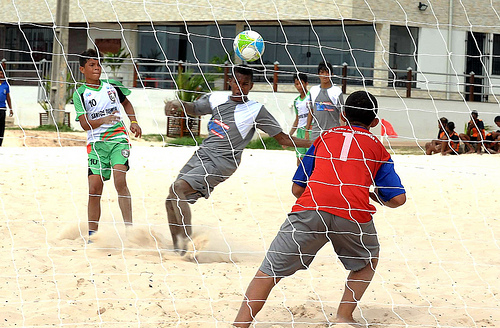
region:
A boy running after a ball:
[163, 63, 310, 262]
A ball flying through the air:
[231, 29, 263, 61]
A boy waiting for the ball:
[231, 90, 408, 324]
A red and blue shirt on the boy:
[287, 123, 404, 223]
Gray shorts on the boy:
[250, 206, 382, 279]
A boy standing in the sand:
[62, 47, 142, 248]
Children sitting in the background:
[425, 108, 498, 157]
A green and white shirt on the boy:
[69, 78, 130, 140]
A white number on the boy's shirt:
[335, 126, 356, 163]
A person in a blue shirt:
[0, 70, 14, 146]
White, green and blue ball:
[231, 26, 268, 64]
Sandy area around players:
[1, 150, 497, 326]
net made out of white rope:
[3, 5, 499, 327]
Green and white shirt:
[68, 75, 133, 137]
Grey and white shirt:
[186, 82, 281, 159]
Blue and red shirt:
[294, 126, 406, 220]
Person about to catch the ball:
[157, 70, 302, 250]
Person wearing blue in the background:
[0, 69, 15, 149]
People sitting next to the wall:
[422, 108, 497, 154]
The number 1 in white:
[328, 123, 353, 167]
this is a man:
[228, 84, 414, 326]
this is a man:
[156, 58, 329, 281]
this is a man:
[29, 40, 173, 244]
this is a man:
[281, 71, 311, 179]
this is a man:
[299, 58, 354, 171]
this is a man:
[429, 103, 456, 171]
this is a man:
[419, 90, 465, 180]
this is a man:
[454, 96, 484, 182]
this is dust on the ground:
[142, 250, 232, 288]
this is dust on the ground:
[106, 204, 176, 274]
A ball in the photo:
[224, 28, 264, 61]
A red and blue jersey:
[316, 147, 376, 214]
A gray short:
[275, 200, 382, 263]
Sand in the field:
[92, 251, 182, 305]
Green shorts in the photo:
[81, 144, 143, 176]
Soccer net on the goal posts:
[26, 252, 193, 321]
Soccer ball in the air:
[234, 29, 274, 71]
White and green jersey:
[71, 77, 149, 142]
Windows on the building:
[328, 22, 431, 74]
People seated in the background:
[418, 82, 497, 159]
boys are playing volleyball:
[62, 3, 439, 295]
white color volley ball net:
[47, 18, 462, 215]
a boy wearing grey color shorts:
[276, 204, 384, 279]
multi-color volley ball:
[228, 25, 270, 68]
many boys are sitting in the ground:
[425, 103, 498, 155]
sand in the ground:
[37, 194, 294, 313]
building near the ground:
[131, 8, 460, 81]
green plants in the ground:
[165, 60, 209, 142]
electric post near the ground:
[42, 7, 70, 127]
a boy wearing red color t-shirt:
[304, 115, 395, 230]